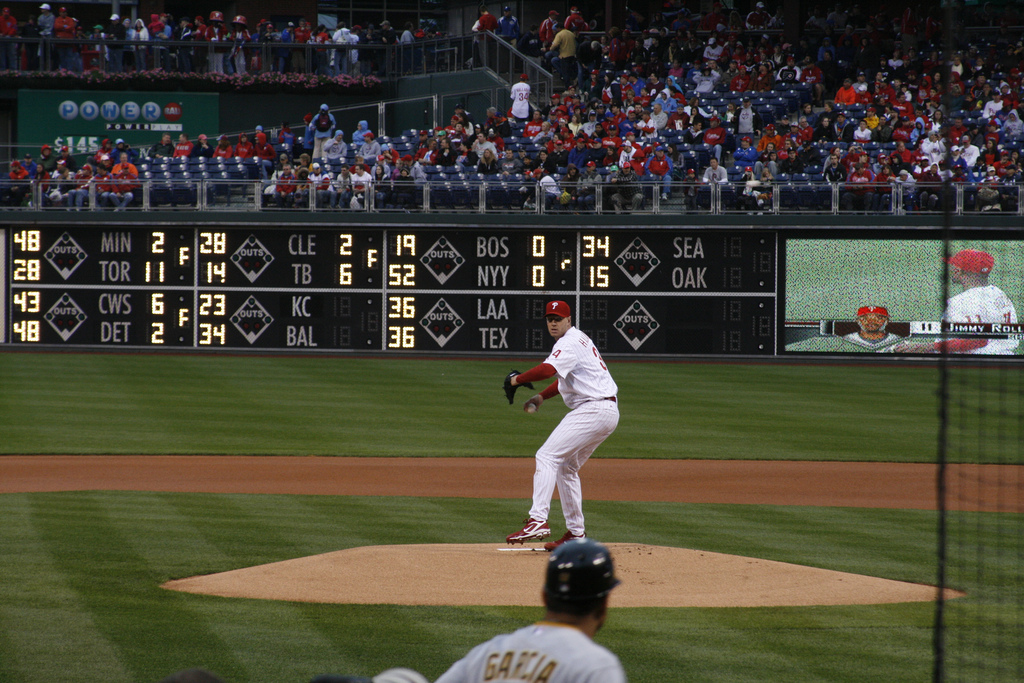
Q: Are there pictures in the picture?
A: No, there are no pictures.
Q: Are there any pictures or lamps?
A: No, there are no pictures or lamps.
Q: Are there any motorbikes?
A: No, there are no motorbikes.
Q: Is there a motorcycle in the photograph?
A: No, there are no motorcycles.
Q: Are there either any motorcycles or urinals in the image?
A: No, there are no motorcycles or urinals.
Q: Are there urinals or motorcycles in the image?
A: No, there are no motorcycles or urinals.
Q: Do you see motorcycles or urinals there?
A: No, there are no motorcycles or urinals.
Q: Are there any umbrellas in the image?
A: No, there are no umbrellas.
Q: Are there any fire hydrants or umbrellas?
A: No, there are no umbrellas or fire hydrants.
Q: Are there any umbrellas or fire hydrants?
A: No, there are no umbrellas or fire hydrants.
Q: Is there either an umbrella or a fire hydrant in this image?
A: No, there are no umbrellas or fire hydrants.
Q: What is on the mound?
A: The pitcher is on the mound.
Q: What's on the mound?
A: The pitcher is on the mound.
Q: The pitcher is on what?
A: The pitcher is on the mound.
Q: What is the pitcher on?
A: The pitcher is on the mound.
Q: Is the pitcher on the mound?
A: Yes, the pitcher is on the mound.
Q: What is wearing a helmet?
A: The pitcher is wearing a helmet.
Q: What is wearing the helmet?
A: The pitcher is wearing a helmet.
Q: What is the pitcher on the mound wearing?
A: The pitcher is wearing a helmet.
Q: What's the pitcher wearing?
A: The pitcher is wearing a helmet.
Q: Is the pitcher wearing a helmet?
A: Yes, the pitcher is wearing a helmet.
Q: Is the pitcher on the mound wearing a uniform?
A: No, the pitcher is wearing a helmet.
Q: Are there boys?
A: No, there are no boys.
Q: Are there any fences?
A: Yes, there is a fence.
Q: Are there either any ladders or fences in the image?
A: Yes, there is a fence.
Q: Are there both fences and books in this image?
A: No, there is a fence but no books.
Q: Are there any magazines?
A: No, there are no magazines.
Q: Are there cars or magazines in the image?
A: No, there are no magazines or cars.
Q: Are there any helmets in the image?
A: Yes, there is a helmet.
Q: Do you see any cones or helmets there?
A: Yes, there is a helmet.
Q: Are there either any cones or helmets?
A: Yes, there is a helmet.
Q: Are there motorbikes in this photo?
A: No, there are no motorbikes.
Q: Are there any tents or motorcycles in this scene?
A: No, there are no motorcycles or tents.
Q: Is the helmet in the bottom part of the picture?
A: Yes, the helmet is in the bottom of the image.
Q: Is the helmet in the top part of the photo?
A: No, the helmet is in the bottom of the image.